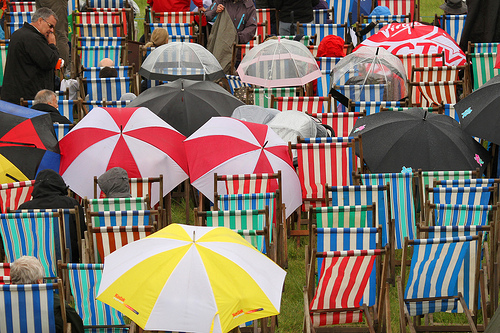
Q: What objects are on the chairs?
A: Umbrellas.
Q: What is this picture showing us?
A: It is showing a very colorful seating arrangement.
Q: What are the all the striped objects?
A: They are green, red and blue striped seats.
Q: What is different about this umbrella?
A: It is only yellow and white.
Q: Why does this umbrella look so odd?
A: Its a classic black umbrella in a field of colored ones.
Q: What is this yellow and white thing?
A: Its a white and yellow umbrella.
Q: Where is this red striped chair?
A: Its in the back of the other chairs.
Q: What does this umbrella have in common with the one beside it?
A: They are both red and white.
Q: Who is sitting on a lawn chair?
A: A man.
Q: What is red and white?
A: The umbrella.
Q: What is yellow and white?
A: A umbrella.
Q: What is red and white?
A: A chair.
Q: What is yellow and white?
A: A umbrella.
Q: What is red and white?
A: A umbrella.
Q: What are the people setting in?
A: Beach chairs.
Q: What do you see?
A: Beach chairs and umbrellas.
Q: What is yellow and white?
A: Umbrella.